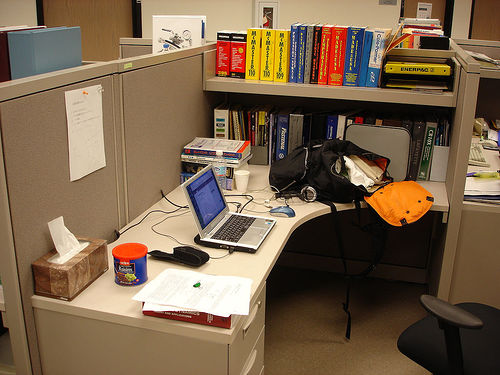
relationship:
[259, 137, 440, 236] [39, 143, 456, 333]
back pack open on desk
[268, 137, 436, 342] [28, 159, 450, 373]
back pack open on a desk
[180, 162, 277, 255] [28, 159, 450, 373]
laptop open on a desk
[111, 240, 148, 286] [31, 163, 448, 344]
can on desk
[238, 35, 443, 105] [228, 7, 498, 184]
books on shelf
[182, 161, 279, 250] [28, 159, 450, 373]
laptop on desk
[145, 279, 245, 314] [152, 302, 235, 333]
paper on book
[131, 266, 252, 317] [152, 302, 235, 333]
paper on book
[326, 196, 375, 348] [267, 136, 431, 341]
strap of backpack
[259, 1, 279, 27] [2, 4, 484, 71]
picture on wall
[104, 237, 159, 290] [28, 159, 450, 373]
can on desk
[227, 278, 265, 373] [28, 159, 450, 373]
drawers on desk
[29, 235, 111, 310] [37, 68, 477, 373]
box on desk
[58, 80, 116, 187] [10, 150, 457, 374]
paper pinned to cubicle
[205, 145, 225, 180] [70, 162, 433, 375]
bottle on desk